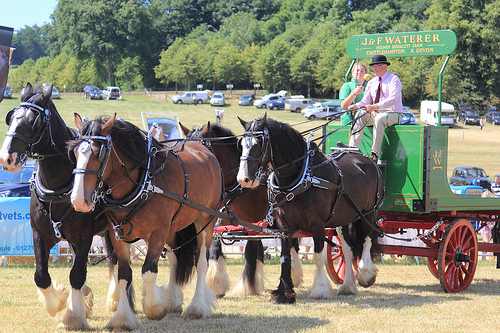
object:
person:
[337, 56, 401, 162]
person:
[339, 62, 369, 126]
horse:
[237, 114, 383, 303]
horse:
[69, 112, 223, 325]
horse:
[1, 82, 94, 333]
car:
[84, 84, 102, 99]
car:
[103, 87, 122, 101]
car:
[173, 90, 208, 104]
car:
[210, 92, 226, 106]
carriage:
[325, 32, 498, 294]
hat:
[368, 54, 390, 67]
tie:
[374, 76, 382, 103]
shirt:
[339, 78, 370, 125]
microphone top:
[364, 74, 371, 81]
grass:
[76, 102, 144, 111]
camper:
[421, 100, 454, 128]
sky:
[0, 2, 48, 22]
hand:
[366, 105, 379, 112]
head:
[69, 113, 112, 212]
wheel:
[436, 218, 478, 293]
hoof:
[275, 290, 296, 302]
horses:
[0, 83, 384, 332]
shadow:
[108, 315, 327, 333]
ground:
[0, 270, 499, 332]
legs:
[279, 207, 377, 300]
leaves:
[196, 37, 338, 79]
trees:
[27, 0, 497, 91]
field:
[0, 87, 495, 166]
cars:
[0, 84, 497, 127]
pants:
[350, 109, 401, 167]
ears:
[236, 113, 267, 130]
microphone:
[361, 75, 369, 87]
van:
[287, 98, 313, 112]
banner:
[1, 196, 61, 255]